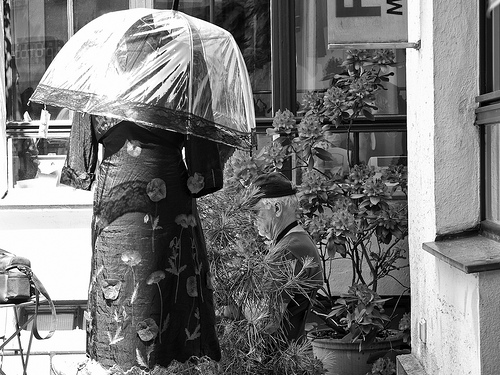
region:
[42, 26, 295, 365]
Woman holding an umbrella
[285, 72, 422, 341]
Plant planted in a vase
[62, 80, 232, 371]
Woman wearing a dress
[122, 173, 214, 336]
Pattern on the dress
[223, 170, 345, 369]
Man sitting on a step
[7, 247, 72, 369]
Bag sitting on a table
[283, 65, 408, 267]
Flowers on the plant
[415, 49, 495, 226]
Plaster wall on building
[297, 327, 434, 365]
The vase is concrete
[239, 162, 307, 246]
man wearing a hat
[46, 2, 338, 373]
Two people outside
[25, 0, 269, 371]
A lady standing under an umbrella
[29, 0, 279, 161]
A clear umbrella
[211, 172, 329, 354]
A man sitting on a bench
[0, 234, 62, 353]
A bag sitting on a table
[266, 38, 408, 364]
A plant growing in a pot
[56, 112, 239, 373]
The woman is wearing a floral dress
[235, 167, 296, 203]
The man is wearing a hat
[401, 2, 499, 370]
Exterior of a building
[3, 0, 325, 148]
Window in front of the lady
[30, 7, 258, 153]
a clear umbrella canopy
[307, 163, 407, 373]
a potted plant and planter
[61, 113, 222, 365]
a dark floral dress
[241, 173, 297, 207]
a man wearing a black cap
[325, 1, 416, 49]
an advertising sign on the wall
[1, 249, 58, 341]
a purse and bag on a table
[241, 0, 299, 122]
a large window behind the man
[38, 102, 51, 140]
a price tag hanging from the umbrella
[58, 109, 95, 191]
the loose sleeve of the floral dress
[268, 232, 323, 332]
a dark shirt on the man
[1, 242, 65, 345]
camera bag on a table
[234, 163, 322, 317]
man in a dark hat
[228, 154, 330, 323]
man behind some bushes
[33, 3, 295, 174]
an open domed shaped umbrella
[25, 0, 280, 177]
a clear umbrella with dark trim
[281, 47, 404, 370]
flower in a large pot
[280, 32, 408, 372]
flower pot with a plant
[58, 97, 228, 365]
dark dress with floral motif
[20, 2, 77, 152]
tag hanging from open umbrella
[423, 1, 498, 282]
window with slanted ledge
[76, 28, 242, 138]
Person holding umbrella.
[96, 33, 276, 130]
Umbrella is clear in color.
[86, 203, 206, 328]
Flowers on person's dress.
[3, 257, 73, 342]
Bag sitting on table.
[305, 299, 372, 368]
Large pot sitting on ground.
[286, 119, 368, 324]
Flowers in large pot.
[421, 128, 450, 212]
White building near people.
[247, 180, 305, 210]
Dark hat on person's head.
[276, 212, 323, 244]
Black strap around person's head.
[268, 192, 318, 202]
Person has light colored hair.